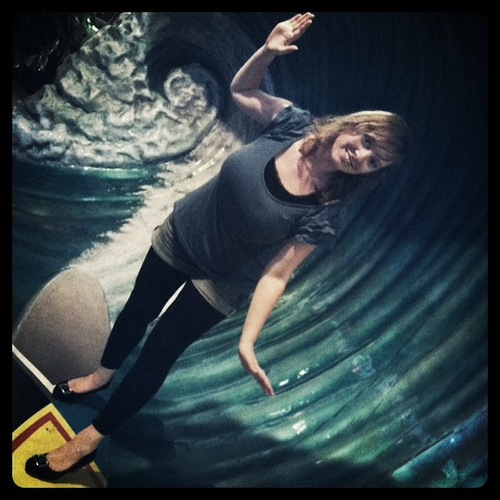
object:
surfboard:
[7, 262, 122, 499]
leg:
[78, 278, 228, 452]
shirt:
[170, 101, 345, 314]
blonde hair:
[298, 109, 410, 203]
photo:
[7, 5, 497, 493]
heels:
[24, 444, 99, 481]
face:
[331, 127, 386, 174]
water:
[14, 13, 225, 199]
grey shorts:
[151, 210, 238, 321]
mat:
[11, 402, 111, 489]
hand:
[237, 346, 273, 399]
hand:
[265, 8, 314, 53]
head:
[328, 109, 412, 173]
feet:
[26, 433, 102, 484]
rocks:
[10, 6, 92, 100]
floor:
[11, 8, 495, 488]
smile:
[342, 145, 354, 170]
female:
[24, 11, 414, 481]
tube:
[9, 6, 489, 486]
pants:
[91, 244, 226, 438]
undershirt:
[264, 156, 324, 205]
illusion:
[13, 13, 490, 495]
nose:
[351, 147, 373, 164]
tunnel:
[14, 10, 490, 488]